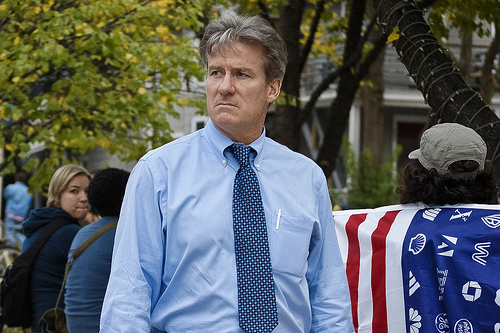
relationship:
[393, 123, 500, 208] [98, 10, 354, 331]
man behind man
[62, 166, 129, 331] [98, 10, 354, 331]
person behind man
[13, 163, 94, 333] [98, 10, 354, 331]
person behind man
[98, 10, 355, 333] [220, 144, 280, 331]
man wearing tie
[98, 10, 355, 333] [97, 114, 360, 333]
man wearing dress shirt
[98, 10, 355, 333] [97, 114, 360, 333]
man standing dress shirt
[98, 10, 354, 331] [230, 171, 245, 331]
man wearing edge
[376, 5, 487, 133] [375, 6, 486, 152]
lights wrapped tree branch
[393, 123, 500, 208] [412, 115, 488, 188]
man wearing hat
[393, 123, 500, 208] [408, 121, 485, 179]
man wearing cap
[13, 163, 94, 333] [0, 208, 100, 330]
person wearing bag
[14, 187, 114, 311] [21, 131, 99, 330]
bag on woman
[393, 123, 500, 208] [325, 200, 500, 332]
man with american flag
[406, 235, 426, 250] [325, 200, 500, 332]
logo on american flag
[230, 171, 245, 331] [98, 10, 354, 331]
edge on man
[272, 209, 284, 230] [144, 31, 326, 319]
pen in man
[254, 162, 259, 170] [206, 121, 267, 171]
button on collar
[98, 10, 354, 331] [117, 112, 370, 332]
man in a shirt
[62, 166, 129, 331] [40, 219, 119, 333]
person carries a bag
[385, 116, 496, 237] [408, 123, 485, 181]
man wearing a cap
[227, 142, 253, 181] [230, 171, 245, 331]
knot in edge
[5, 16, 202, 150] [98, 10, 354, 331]
trees behind a man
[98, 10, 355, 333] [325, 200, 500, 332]
man next to american flag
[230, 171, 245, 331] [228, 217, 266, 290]
edge of a tie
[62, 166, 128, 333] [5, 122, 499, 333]
person in background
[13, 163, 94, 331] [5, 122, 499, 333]
person in background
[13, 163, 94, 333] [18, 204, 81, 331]
person wearing a hoodie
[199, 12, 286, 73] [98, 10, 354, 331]
hair of man